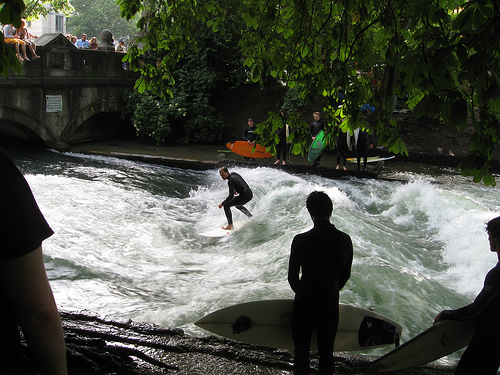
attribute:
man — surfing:
[213, 165, 256, 230]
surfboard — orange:
[224, 138, 276, 161]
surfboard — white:
[202, 217, 250, 239]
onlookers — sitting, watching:
[4, 18, 43, 63]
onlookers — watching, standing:
[61, 31, 129, 52]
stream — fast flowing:
[5, 150, 498, 339]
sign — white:
[44, 93, 65, 113]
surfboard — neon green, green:
[307, 126, 336, 163]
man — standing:
[285, 190, 354, 373]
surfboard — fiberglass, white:
[193, 297, 402, 352]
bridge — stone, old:
[0, 32, 145, 149]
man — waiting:
[244, 116, 259, 163]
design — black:
[231, 313, 272, 336]